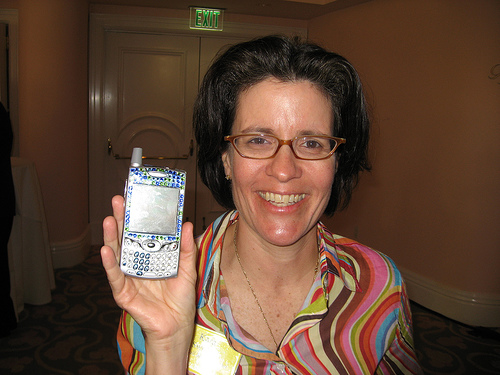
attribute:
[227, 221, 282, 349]
chain — long, gold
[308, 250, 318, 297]
chain — long, gold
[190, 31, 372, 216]
hair — dark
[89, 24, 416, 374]
lady — happy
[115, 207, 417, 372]
shirt — striped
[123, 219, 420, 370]
shirt — colorful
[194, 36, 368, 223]
hair — black, short, dark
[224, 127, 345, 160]
glasses — old fashioned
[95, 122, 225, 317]
panic — gold